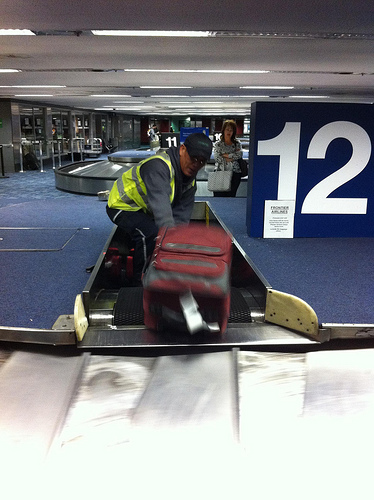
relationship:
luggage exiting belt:
[140, 226, 232, 343] [115, 287, 141, 323]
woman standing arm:
[212, 123, 247, 196] [227, 152, 242, 158]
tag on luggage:
[179, 294, 203, 331] [140, 226, 232, 343]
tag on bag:
[179, 294, 203, 331] [205, 156, 232, 192]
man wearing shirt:
[105, 133, 214, 288] [135, 144, 199, 231]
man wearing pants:
[105, 133, 214, 288] [102, 202, 168, 280]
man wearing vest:
[105, 133, 214, 288] [106, 150, 176, 214]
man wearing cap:
[115, 133, 238, 250] [184, 132, 213, 161]